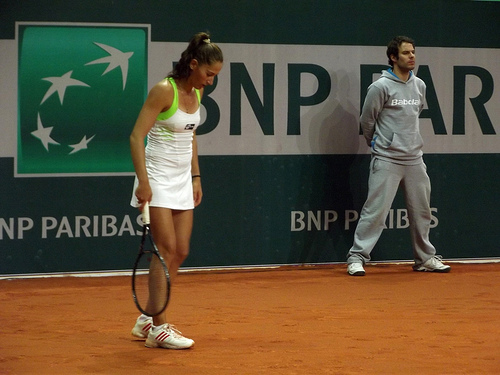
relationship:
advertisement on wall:
[0, 20, 497, 240] [6, 7, 496, 264]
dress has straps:
[130, 76, 207, 210] [157, 74, 207, 129]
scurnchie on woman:
[197, 34, 213, 46] [114, 26, 229, 358]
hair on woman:
[168, 33, 223, 70] [131, 33, 224, 351]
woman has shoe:
[131, 33, 224, 351] [145, 323, 195, 350]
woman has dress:
[131, 33, 224, 351] [127, 75, 202, 212]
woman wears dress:
[114, 26, 229, 358] [122, 75, 202, 212]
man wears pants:
[335, 24, 463, 284] [343, 155, 433, 270]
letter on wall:
[1, 208, 122, 247] [4, 141, 498, 273]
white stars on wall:
[27, 30, 134, 164] [6, 7, 496, 264]